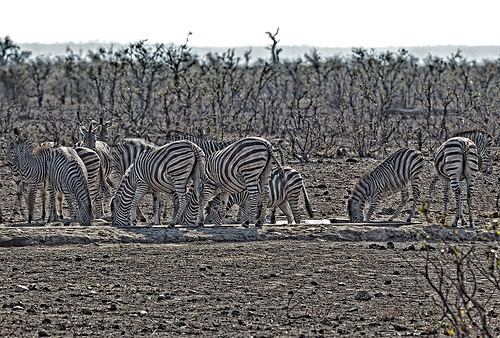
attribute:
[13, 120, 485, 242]
group — large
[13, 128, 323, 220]
zebras — camouflaged, drinking, together, standing, bending, eating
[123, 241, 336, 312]
soil — barren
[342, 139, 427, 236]
zebra — bending, drinking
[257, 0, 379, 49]
skyline — foggy, open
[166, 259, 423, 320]
ground — gray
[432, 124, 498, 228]
zebra — alone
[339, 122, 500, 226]
zebras — relaxing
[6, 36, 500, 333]
environment — dry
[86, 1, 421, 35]
sky — hazy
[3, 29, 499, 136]
vegetation — little